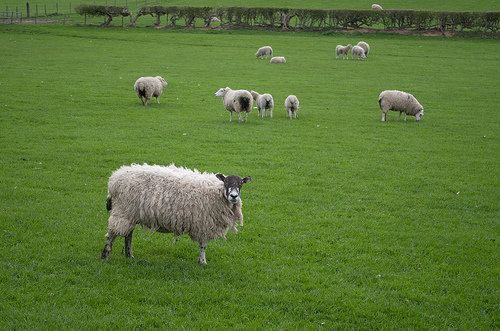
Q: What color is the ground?
A: Green.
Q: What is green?
A: Grass.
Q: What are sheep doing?
A: Grazing.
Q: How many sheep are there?
A: Eleven.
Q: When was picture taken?
A: Daytime.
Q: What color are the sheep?
A: White.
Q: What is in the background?
A: Trees.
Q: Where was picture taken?
A: In a field.